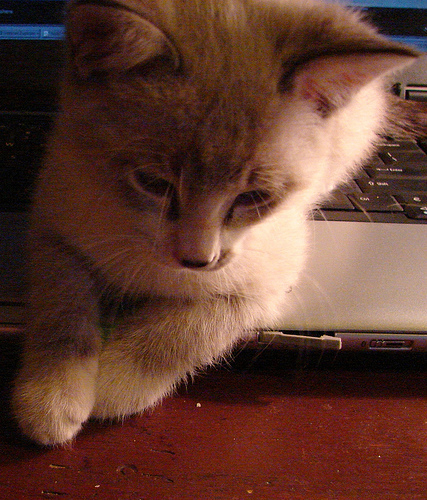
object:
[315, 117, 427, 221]
keyboard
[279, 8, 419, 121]
ear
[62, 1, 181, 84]
ear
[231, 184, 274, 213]
eye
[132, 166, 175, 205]
eye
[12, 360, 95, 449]
paw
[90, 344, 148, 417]
paw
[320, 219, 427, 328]
surface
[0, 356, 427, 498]
table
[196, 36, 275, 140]
fur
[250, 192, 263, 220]
whiskers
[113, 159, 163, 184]
whiskers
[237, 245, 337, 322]
whiskers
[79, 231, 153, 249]
whiskers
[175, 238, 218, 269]
nose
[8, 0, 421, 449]
kitten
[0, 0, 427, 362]
laptop